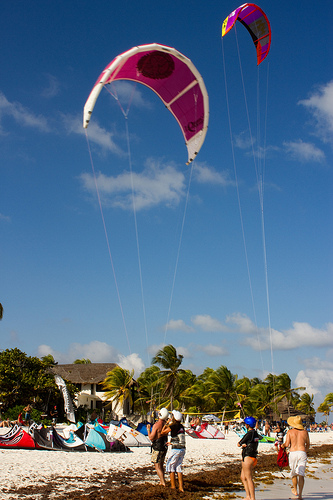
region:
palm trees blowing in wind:
[186, 366, 236, 410]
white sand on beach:
[13, 448, 69, 477]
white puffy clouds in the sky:
[228, 311, 326, 354]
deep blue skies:
[10, 266, 98, 324]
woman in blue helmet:
[236, 415, 257, 498]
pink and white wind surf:
[82, 39, 209, 166]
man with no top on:
[276, 414, 309, 499]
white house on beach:
[49, 362, 141, 424]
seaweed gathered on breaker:
[191, 470, 241, 490]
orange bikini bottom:
[240, 454, 259, 466]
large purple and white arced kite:
[83, 39, 221, 157]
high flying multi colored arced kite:
[221, 2, 275, 54]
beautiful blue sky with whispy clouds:
[5, 0, 330, 366]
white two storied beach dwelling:
[52, 356, 132, 423]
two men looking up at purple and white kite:
[130, 402, 189, 496]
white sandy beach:
[5, 424, 330, 494]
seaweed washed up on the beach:
[23, 450, 332, 499]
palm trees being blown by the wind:
[105, 346, 331, 423]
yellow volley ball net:
[164, 405, 244, 432]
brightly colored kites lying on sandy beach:
[0, 417, 151, 451]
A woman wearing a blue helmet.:
[236, 411, 259, 499]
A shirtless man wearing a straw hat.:
[281, 415, 314, 497]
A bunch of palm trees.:
[101, 341, 315, 416]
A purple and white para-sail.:
[63, 24, 217, 167]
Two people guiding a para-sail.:
[66, 37, 217, 480]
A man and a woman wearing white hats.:
[139, 396, 189, 495]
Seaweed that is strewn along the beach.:
[92, 482, 155, 496]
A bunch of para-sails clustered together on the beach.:
[10, 421, 137, 451]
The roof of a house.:
[62, 359, 112, 386]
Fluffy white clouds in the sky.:
[221, 308, 331, 359]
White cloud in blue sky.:
[11, 166, 214, 225]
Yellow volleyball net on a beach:
[152, 402, 245, 441]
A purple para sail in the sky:
[67, 26, 211, 170]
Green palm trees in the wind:
[111, 361, 295, 426]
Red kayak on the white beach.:
[0, 417, 39, 466]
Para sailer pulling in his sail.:
[217, 2, 290, 457]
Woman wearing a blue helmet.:
[234, 408, 263, 490]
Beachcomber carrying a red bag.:
[271, 409, 310, 499]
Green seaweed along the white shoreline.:
[96, 458, 331, 497]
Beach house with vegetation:
[14, 360, 140, 422]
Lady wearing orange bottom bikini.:
[240, 411, 263, 495]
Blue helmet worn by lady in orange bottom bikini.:
[240, 417, 259, 429]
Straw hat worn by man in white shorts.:
[282, 412, 311, 434]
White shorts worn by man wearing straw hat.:
[286, 450, 310, 476]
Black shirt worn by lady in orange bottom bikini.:
[241, 428, 264, 459]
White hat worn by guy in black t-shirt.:
[172, 408, 184, 423]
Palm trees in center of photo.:
[105, 359, 304, 413]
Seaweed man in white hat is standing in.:
[83, 470, 259, 492]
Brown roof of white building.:
[55, 362, 125, 384]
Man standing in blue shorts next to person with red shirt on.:
[26, 401, 33, 421]